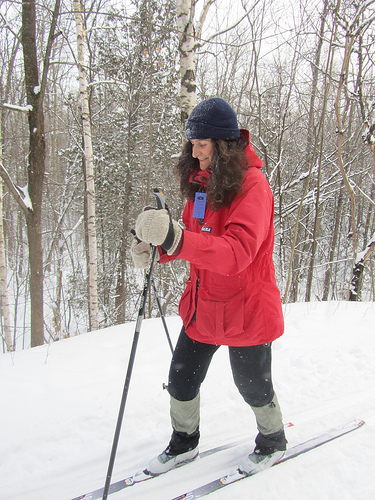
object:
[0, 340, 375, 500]
ground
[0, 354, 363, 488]
slopes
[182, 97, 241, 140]
hat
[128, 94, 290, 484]
woman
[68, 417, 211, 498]
ski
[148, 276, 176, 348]
pole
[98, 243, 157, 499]
pole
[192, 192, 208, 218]
tag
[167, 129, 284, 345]
coat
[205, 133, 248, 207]
hair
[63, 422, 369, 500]
skis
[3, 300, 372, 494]
snow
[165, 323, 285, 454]
pants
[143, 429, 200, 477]
boots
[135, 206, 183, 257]
gloves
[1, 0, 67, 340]
trees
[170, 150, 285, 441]
clothes